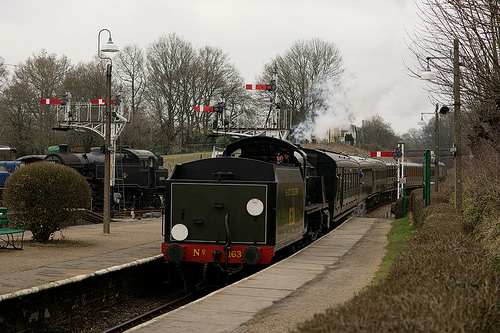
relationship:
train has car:
[158, 100, 470, 282] [158, 151, 312, 270]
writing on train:
[185, 241, 246, 259] [158, 100, 470, 282]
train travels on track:
[158, 100, 470, 282] [80, 287, 220, 317]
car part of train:
[318, 146, 371, 215] [158, 100, 470, 282]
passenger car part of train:
[402, 160, 426, 191] [158, 100, 470, 282]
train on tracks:
[158, 100, 470, 282] [61, 260, 223, 330]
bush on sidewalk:
[0, 157, 92, 244] [0, 206, 170, 297]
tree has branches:
[141, 32, 194, 154] [143, 30, 198, 111]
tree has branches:
[407, 0, 498, 139] [402, 0, 497, 92]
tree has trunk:
[141, 32, 194, 154] [163, 94, 176, 154]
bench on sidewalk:
[0, 226, 25, 248] [0, 213, 163, 298]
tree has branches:
[407, 0, 498, 139] [284, 35, 349, 88]